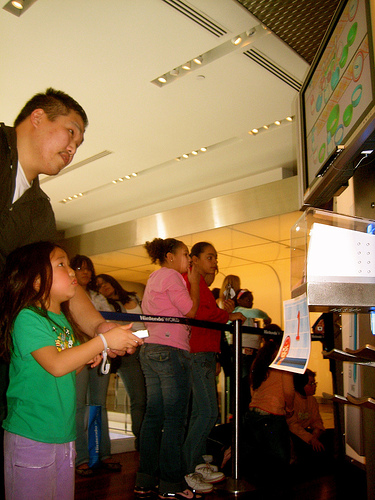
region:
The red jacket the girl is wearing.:
[191, 270, 223, 350]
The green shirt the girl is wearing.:
[5, 304, 70, 439]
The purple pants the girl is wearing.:
[4, 435, 74, 495]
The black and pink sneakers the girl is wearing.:
[128, 474, 199, 491]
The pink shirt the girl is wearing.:
[138, 264, 187, 344]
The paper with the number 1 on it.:
[280, 297, 310, 371]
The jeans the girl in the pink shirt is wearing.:
[135, 342, 185, 487]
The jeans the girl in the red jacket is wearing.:
[189, 351, 217, 468]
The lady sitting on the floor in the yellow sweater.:
[290, 356, 343, 474]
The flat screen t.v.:
[284, 2, 365, 213]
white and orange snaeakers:
[190, 457, 228, 498]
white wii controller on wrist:
[31, 318, 154, 408]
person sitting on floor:
[261, 361, 344, 481]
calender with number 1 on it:
[256, 295, 310, 401]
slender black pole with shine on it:
[158, 318, 266, 492]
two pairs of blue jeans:
[125, 349, 225, 482]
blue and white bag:
[66, 397, 120, 477]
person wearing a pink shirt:
[111, 266, 192, 364]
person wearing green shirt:
[15, 311, 70, 417]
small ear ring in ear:
[148, 255, 181, 268]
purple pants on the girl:
[2, 427, 76, 499]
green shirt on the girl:
[2, 309, 81, 444]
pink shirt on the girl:
[138, 265, 195, 354]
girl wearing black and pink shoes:
[131, 481, 206, 499]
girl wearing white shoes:
[180, 463, 227, 491]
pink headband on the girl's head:
[233, 286, 249, 301]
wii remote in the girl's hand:
[128, 327, 152, 342]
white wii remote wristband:
[95, 329, 112, 377]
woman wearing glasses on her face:
[74, 263, 93, 273]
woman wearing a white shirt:
[123, 303, 147, 330]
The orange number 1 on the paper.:
[288, 306, 306, 351]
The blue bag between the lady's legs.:
[84, 401, 106, 466]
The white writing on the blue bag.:
[89, 417, 102, 458]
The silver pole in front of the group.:
[220, 314, 258, 497]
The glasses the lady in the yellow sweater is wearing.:
[307, 377, 317, 387]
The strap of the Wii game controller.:
[100, 330, 111, 379]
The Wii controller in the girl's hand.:
[129, 325, 149, 337]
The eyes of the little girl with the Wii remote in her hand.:
[54, 259, 71, 270]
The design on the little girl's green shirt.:
[35, 315, 75, 351]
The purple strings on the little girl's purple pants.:
[61, 442, 74, 468]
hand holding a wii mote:
[94, 310, 160, 382]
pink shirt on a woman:
[135, 258, 196, 357]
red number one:
[291, 308, 304, 347]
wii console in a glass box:
[298, 213, 373, 282]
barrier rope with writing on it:
[96, 290, 229, 339]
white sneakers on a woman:
[183, 459, 227, 493]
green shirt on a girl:
[13, 289, 86, 454]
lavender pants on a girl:
[6, 430, 78, 498]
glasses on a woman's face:
[72, 254, 93, 274]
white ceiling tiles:
[101, 245, 133, 270]